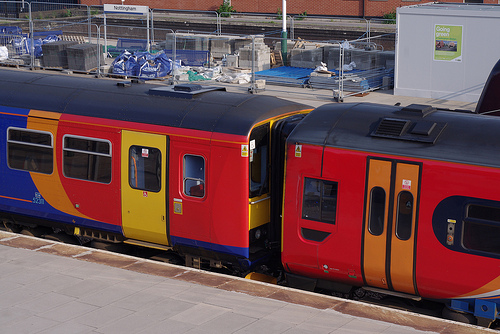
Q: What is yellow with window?
A: Door.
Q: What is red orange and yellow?
A: Train car.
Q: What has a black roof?
A: Train car.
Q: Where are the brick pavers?
A: Train platform.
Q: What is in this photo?
A: A train.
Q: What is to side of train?
A: The ground.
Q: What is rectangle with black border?
A: Yellow door.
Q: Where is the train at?
A: On the tracks.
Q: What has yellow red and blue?
A: The train.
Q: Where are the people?
A: On the train.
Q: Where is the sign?
A: On the building.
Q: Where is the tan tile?
A: On the sidewalk.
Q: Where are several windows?
A: On the train.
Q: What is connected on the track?
A: Train cars.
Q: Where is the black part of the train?
A: On top.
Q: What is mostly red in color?
A: Train car.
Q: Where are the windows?
A: On the side of the train car.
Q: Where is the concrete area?
A: Next to the train.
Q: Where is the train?
A: On the track.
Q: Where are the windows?
A: On the train.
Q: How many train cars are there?
A: Two.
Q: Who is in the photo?
A: Nobody.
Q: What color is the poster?
A: Green.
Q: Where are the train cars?
A: On the track.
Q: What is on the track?
A: The train cars.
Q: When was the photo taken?
A: Daytime.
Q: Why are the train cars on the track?
A: So they can move.